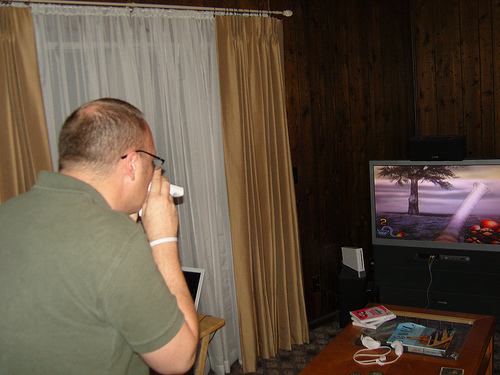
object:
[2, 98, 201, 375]
man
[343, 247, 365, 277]
wii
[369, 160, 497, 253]
televison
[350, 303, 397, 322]
book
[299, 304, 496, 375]
table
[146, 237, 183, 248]
band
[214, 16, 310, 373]
curtains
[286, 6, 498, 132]
wood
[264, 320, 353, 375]
carpet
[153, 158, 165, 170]
spectacles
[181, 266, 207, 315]
laptop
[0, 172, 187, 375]
shirt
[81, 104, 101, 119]
spot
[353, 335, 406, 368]
controller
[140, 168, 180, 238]
hand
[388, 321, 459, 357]
magazine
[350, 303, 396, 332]
stack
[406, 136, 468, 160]
speaker